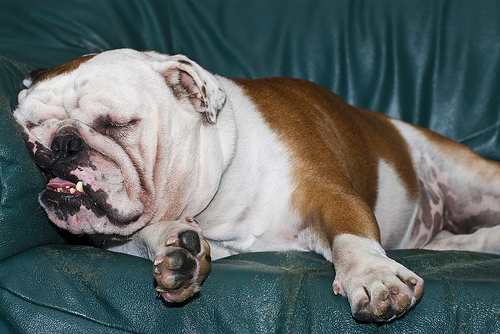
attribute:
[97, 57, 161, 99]
hair — white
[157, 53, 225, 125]
spots — brown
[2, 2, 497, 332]
couch — green, leather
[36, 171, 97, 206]
mouth — open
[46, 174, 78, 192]
tongue — sticking out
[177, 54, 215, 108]
spots — brown